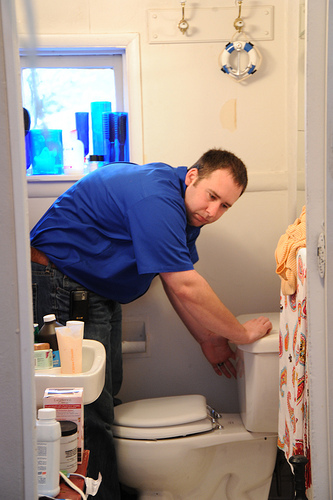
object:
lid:
[110, 395, 213, 442]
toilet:
[110, 313, 281, 500]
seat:
[106, 392, 221, 500]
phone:
[66, 286, 89, 326]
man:
[28, 148, 273, 500]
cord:
[59, 470, 104, 500]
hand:
[229, 314, 273, 345]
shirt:
[28, 159, 204, 312]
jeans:
[30, 229, 124, 499]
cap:
[42, 313, 58, 325]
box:
[43, 387, 89, 465]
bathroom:
[1, 0, 332, 498]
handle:
[289, 454, 306, 500]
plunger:
[288, 450, 309, 500]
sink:
[28, 424, 62, 498]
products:
[28, 313, 107, 500]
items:
[18, 42, 130, 174]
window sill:
[26, 172, 120, 201]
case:
[70, 282, 89, 324]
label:
[63, 446, 80, 471]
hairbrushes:
[102, 109, 127, 165]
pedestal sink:
[33, 339, 107, 409]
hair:
[186, 148, 249, 199]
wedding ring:
[219, 361, 226, 368]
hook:
[177, 17, 190, 33]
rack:
[178, 1, 189, 32]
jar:
[108, 111, 126, 165]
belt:
[32, 246, 55, 268]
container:
[54, 323, 84, 374]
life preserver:
[21, 129, 63, 178]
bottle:
[34, 313, 85, 372]